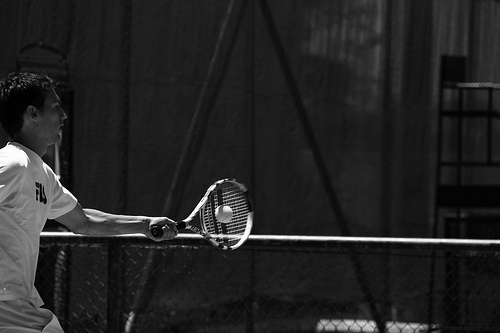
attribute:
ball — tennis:
[211, 200, 233, 226]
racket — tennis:
[151, 178, 256, 251]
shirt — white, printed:
[1, 141, 79, 332]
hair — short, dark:
[0, 71, 61, 135]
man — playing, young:
[0, 71, 180, 332]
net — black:
[37, 231, 498, 332]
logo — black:
[34, 181, 50, 207]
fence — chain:
[33, 232, 499, 330]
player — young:
[1, 72, 178, 332]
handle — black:
[149, 218, 188, 240]